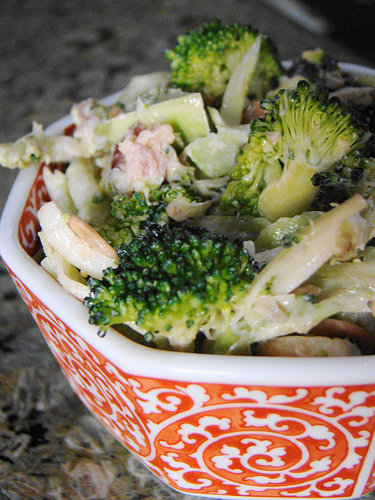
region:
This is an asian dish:
[79, 175, 298, 331]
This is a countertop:
[43, 403, 114, 498]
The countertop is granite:
[37, 405, 80, 496]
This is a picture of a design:
[142, 401, 284, 492]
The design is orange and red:
[117, 414, 239, 461]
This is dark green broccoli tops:
[98, 189, 230, 285]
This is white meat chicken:
[114, 167, 178, 173]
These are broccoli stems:
[97, 110, 149, 134]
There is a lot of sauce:
[131, 170, 296, 294]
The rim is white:
[137, 363, 235, 415]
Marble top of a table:
[14, 458, 56, 498]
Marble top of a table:
[71, 458, 81, 487]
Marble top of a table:
[104, 467, 136, 496]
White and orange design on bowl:
[179, 412, 240, 467]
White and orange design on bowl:
[245, 408, 308, 473]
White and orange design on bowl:
[314, 443, 338, 486]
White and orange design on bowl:
[78, 360, 177, 426]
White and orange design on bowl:
[82, 354, 313, 484]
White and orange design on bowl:
[345, 389, 374, 471]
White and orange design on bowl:
[11, 274, 73, 355]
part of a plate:
[300, 443, 306, 452]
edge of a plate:
[177, 403, 185, 416]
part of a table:
[73, 424, 84, 434]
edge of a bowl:
[224, 363, 231, 377]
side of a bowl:
[203, 448, 219, 473]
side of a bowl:
[173, 416, 181, 435]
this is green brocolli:
[66, 227, 246, 331]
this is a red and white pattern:
[197, 416, 277, 470]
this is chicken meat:
[115, 126, 185, 180]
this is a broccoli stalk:
[238, 151, 314, 212]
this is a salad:
[36, 198, 312, 321]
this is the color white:
[43, 277, 52, 302]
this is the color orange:
[164, 432, 172, 438]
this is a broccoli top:
[134, 240, 178, 281]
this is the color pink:
[144, 142, 153, 158]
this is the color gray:
[49, 460, 59, 466]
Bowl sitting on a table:
[8, 11, 368, 487]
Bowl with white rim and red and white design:
[4, 45, 374, 492]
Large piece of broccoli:
[89, 225, 283, 348]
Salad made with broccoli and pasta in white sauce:
[11, 19, 368, 353]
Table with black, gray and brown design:
[6, 18, 364, 495]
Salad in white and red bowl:
[4, 21, 374, 496]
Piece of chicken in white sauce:
[107, 122, 192, 190]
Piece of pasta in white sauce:
[231, 198, 373, 336]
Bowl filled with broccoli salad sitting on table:
[11, 21, 372, 492]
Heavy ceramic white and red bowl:
[4, 53, 373, 494]